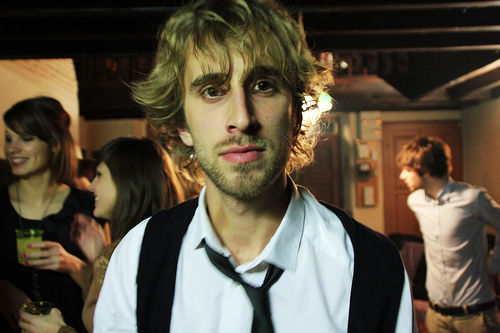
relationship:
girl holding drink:
[0, 95, 112, 333] [14, 223, 54, 276]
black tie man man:
[233, 272, 281, 331] [129, 14, 362, 327]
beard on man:
[177, 129, 308, 201] [67, 39, 430, 314]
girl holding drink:
[0, 88, 76, 325] [14, 214, 56, 265]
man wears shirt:
[87, 4, 416, 332] [89, 171, 419, 331]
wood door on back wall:
[378, 122, 426, 230] [318, 108, 400, 234]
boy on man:
[396, 136, 500, 333] [426, 298, 498, 329]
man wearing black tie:
[87, 4, 416, 332] [205, 243, 286, 333]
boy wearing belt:
[387, 132, 498, 332] [423, 297, 489, 322]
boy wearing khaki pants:
[396, 136, 500, 333] [418, 292, 498, 330]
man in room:
[92, 0, 412, 332] [6, 106, 496, 333]